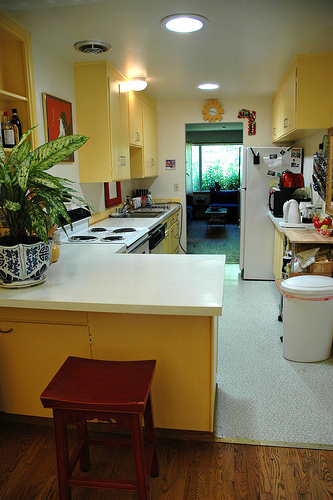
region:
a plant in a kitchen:
[3, 146, 117, 283]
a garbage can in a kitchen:
[254, 268, 329, 361]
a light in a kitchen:
[114, 69, 187, 106]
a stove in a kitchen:
[75, 169, 194, 251]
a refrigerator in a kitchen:
[224, 148, 319, 249]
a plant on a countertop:
[10, 150, 100, 267]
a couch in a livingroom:
[197, 167, 249, 236]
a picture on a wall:
[38, 65, 109, 174]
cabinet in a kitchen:
[245, 78, 318, 145]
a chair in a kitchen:
[36, 364, 173, 473]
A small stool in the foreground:
[33, 340, 170, 496]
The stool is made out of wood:
[34, 342, 171, 496]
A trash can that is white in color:
[261, 268, 331, 369]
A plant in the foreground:
[3, 120, 98, 289]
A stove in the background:
[56, 197, 154, 264]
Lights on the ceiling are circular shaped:
[150, 3, 239, 101]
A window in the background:
[185, 143, 240, 189]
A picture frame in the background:
[39, 90, 81, 166]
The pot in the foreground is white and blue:
[3, 232, 61, 293]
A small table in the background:
[198, 196, 233, 244]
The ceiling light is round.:
[186, 73, 227, 97]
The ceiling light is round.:
[156, 7, 212, 48]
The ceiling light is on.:
[187, 67, 225, 95]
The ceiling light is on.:
[154, 7, 224, 57]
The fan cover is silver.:
[55, 24, 118, 62]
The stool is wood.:
[32, 353, 167, 499]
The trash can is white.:
[272, 271, 331, 368]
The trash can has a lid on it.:
[274, 269, 332, 366]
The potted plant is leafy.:
[0, 121, 91, 296]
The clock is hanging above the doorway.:
[179, 95, 247, 268]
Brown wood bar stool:
[38, 354, 159, 499]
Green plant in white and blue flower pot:
[0, 122, 94, 288]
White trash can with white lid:
[275, 274, 332, 362]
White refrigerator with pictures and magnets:
[238, 146, 301, 280]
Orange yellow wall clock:
[200, 99, 224, 123]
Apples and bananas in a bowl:
[310, 214, 330, 236]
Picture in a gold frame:
[41, 91, 74, 162]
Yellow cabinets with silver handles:
[76, 60, 159, 184]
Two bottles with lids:
[1, 107, 22, 149]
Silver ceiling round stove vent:
[74, 40, 111, 56]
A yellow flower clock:
[199, 95, 225, 122]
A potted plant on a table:
[0, 124, 93, 287]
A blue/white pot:
[0, 230, 54, 287]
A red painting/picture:
[36, 86, 76, 163]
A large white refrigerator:
[234, 139, 304, 281]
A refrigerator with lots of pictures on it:
[236, 141, 303, 282]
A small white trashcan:
[273, 267, 327, 363]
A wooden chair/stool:
[25, 350, 168, 494]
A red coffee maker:
[271, 164, 303, 189]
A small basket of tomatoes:
[305, 210, 329, 240]